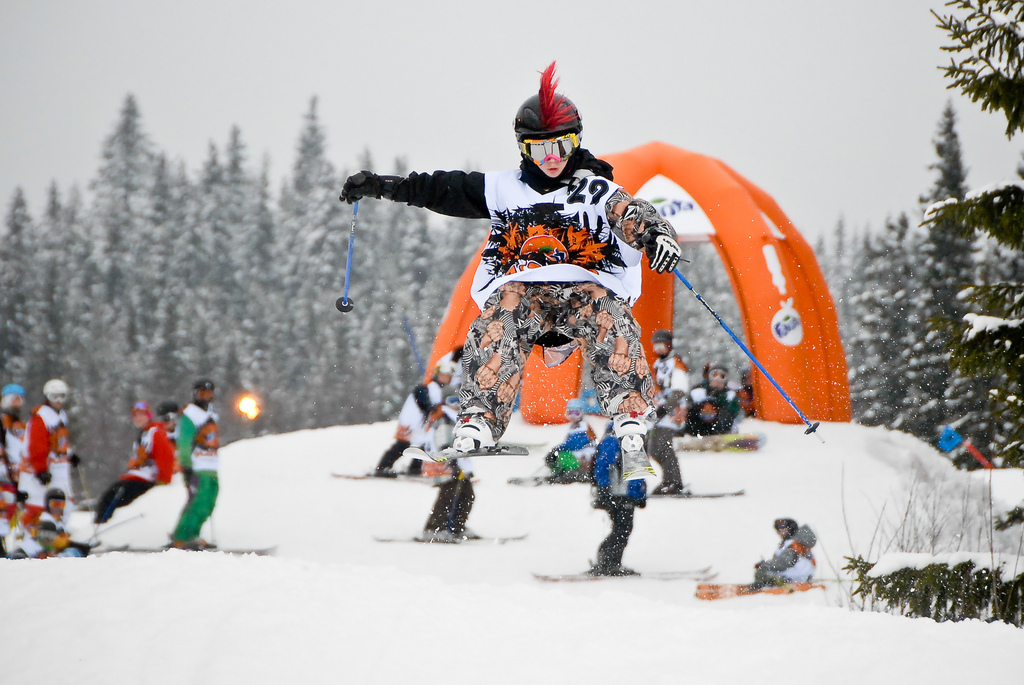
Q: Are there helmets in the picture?
A: Yes, there is a helmet.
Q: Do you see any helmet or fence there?
A: Yes, there is a helmet.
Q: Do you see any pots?
A: No, there are no pots.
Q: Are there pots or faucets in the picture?
A: No, there are no pots or faucets.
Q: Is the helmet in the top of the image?
A: Yes, the helmet is in the top of the image.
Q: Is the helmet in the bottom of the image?
A: No, the helmet is in the top of the image.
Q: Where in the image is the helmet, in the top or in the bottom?
A: The helmet is in the top of the image.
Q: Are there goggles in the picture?
A: Yes, there are goggles.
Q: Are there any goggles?
A: Yes, there are goggles.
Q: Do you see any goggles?
A: Yes, there are goggles.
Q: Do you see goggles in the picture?
A: Yes, there are goggles.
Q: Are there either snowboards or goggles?
A: Yes, there are goggles.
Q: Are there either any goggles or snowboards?
A: Yes, there are goggles.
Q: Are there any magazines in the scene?
A: No, there are no magazines.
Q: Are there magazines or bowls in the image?
A: No, there are no magazines or bowls.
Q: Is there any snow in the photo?
A: Yes, there is snow.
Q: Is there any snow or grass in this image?
A: Yes, there is snow.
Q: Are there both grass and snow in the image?
A: No, there is snow but no grass.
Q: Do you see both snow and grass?
A: No, there is snow but no grass.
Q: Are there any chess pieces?
A: No, there are no chess pieces.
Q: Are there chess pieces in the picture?
A: No, there are no chess pieces.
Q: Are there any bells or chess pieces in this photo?
A: No, there are no chess pieces or bells.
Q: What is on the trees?
A: The snow is on the trees.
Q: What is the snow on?
A: The snow is on the trees.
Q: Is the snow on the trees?
A: Yes, the snow is on the trees.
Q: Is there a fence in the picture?
A: No, there are no fences.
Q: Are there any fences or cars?
A: No, there are no fences or cars.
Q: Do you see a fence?
A: No, there are no fences.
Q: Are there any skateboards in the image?
A: No, there are no skateboards.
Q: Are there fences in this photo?
A: No, there are no fences.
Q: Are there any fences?
A: No, there are no fences.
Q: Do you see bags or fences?
A: No, there are no fences or bags.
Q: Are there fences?
A: No, there are no fences.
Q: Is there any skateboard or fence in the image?
A: No, there are no fences or skateboards.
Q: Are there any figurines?
A: No, there are no figurines.